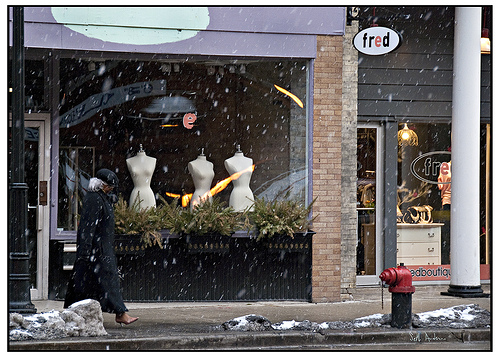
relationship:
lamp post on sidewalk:
[8, 4, 38, 314] [235, 287, 309, 317]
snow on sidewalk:
[118, 284, 334, 311] [31, 289, 218, 354]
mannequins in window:
[102, 129, 170, 209] [50, 60, 302, 286]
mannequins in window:
[187, 141, 216, 216] [50, 60, 302, 286]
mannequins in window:
[211, 143, 272, 224] [50, 60, 302, 286]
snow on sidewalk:
[28, 305, 85, 348] [84, 282, 498, 339]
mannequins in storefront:
[125, 152, 158, 212] [31, 55, 308, 307]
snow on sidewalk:
[412, 289, 468, 328] [149, 300, 343, 354]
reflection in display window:
[61, 62, 199, 132] [51, 56, 308, 241]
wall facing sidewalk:
[304, 26, 344, 303] [6, 278, 491, 353]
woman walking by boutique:
[62, 162, 137, 332] [8, 4, 358, 305]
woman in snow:
[62, 162, 137, 332] [91, 62, 107, 76]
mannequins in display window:
[187, 156, 216, 214] [31, 63, 312, 300]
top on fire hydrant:
[379, 260, 415, 291] [378, 259, 415, 329]